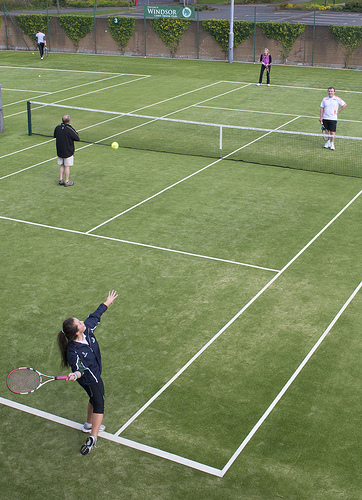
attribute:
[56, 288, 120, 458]
person — playing, hitting, serving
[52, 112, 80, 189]
person — playing, man, older, middle-aged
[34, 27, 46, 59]
person — playing, walking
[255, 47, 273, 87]
person — playing, waiting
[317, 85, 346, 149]
person — playing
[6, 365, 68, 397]
racket — red, white, pink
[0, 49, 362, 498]
court — green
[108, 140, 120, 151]
ball — green, airborn, yellow, flying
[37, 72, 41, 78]
ball — green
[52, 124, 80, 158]
jacket — black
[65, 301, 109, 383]
jacket — blue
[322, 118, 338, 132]
shorts — black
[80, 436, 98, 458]
sneaker — white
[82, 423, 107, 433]
sneaker — white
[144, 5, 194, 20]
sign — green, white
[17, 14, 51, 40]
ivy — growing, green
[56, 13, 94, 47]
ivy — growing, green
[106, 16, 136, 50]
ivy — growing, green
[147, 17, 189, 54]
ivy — growing, green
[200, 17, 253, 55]
ivy — growing, green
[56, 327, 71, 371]
ponytail — brown